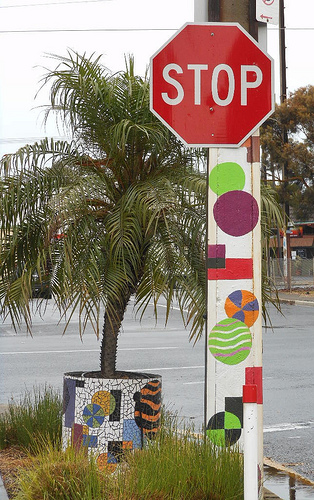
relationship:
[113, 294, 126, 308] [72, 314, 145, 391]
spines on tree trunk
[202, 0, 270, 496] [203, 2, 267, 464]
circle on a post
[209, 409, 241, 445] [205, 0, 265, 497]
circle on a pole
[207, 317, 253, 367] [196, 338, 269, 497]
circle on a post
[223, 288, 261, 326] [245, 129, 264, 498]
circle on a post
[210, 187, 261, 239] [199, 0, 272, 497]
circle on a post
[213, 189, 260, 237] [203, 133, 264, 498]
circle on a post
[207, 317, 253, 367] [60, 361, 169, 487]
circle on a post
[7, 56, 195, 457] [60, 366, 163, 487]
palm tree in post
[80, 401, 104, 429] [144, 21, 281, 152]
design on sign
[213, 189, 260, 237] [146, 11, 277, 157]
circle on sign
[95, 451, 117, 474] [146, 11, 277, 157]
design on sign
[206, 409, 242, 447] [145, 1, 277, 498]
circle on sign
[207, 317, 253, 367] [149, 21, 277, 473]
circle on sign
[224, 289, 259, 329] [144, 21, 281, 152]
circle on sign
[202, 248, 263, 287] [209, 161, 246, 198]
design on circle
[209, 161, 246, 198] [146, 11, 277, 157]
circle on sign